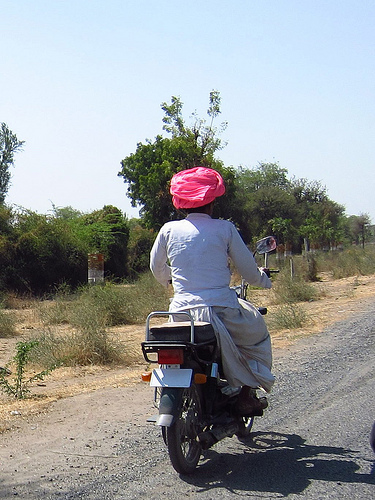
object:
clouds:
[0, 0, 373, 225]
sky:
[0, 1, 373, 226]